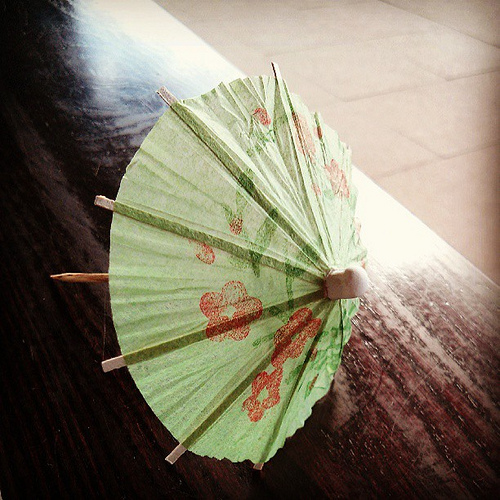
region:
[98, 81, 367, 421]
this is a cocktail umbrella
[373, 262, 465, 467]
this is a brown table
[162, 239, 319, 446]
this is a green umbrella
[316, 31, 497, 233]
this are concrete slubs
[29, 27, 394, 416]
this is an outdoor image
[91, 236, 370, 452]
i love this image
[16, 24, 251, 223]
what a lovely shot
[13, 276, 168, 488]
this a good looking photo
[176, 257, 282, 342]
the weather looks sunnyred flowers on the umbrealla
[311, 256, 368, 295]
this is the tip of the umbrella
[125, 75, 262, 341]
green cocktail umbrella decoration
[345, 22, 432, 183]
A cream colored tile floor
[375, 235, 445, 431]
dark wood table top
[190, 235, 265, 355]
A red flower design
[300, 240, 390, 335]
Wooden top of umbrella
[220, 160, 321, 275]
Darker green leaves design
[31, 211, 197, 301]
pointed center of umbrella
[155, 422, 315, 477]
ruffled edge of the paper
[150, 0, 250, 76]
Edge of table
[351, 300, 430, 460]
scratches on table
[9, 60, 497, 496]
a green umbrella on a wood table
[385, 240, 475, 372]
light shines on table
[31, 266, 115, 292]
a sharp wooden stake on a table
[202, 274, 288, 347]
red flower on an umbrella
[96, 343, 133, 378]
wooden support on an umbrella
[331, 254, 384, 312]
a wooden knob on top of an umbrella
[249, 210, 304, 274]
a green leaf on an umbrella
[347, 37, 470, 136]
white tile on the floor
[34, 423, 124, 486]
lines in wooden table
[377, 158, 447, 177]
gray lines on white tile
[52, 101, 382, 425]
Umbrella for a drink.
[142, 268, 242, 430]
Green paper umbrella.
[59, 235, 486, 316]
Toothpick umbrella for a cocktail.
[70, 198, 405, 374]
Opened toothpick umbrella.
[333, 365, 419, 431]
Wooden bar with a umbrella garnish on it.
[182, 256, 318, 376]
Red flowers on the toothpick umbrella.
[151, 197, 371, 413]
Green tissue paper.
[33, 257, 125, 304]
Toothpick.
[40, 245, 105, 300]
Wooden toothpick stem.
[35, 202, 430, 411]
Toothpick umbrella on its side.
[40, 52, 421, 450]
open umbrella on top of table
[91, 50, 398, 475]
umbrella made of folded paper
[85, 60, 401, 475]
green umbrella with red flowers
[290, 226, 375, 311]
white knob on top of umbrella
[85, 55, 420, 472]
ribs like a spoke under umbrella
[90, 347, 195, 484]
umbrella ribs extending beyond edge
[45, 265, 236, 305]
handle of umbrella resting on table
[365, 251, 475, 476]
grain of wood showing through dark stain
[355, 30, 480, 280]
table next to floor with light tiles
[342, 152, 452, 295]
light reflecting off edge of table